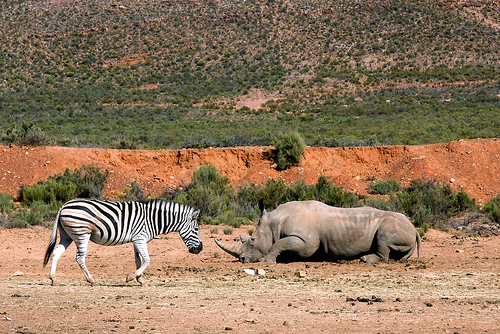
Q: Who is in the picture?
A: A zebra and a rhino.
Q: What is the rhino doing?
A: Lying down.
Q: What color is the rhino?
A: Gray.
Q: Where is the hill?
A: Behind the rhino.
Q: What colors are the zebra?
A: Black and white.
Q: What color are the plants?
A: Green.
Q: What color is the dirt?
A: Brown.